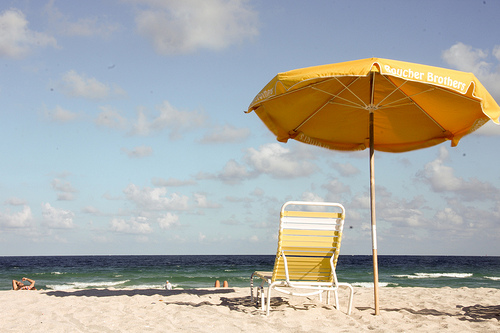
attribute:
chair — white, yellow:
[251, 213, 310, 281]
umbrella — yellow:
[370, 27, 428, 126]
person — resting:
[14, 261, 39, 293]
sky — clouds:
[169, 145, 275, 248]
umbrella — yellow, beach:
[250, 49, 498, 309]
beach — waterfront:
[19, 291, 469, 330]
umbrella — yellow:
[241, 54, 492, 329]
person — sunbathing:
[6, 270, 52, 296]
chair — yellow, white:
[256, 199, 359, 330]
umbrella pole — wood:
[362, 104, 385, 310]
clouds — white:
[38, 171, 222, 250]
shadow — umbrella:
[47, 286, 237, 297]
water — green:
[65, 257, 220, 276]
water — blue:
[121, 253, 216, 266]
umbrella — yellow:
[245, 55, 497, 180]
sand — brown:
[127, 310, 170, 326]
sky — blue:
[24, 95, 244, 190]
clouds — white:
[92, 171, 222, 241]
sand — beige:
[19, 278, 279, 328]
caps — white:
[390, 263, 482, 296]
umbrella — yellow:
[236, 45, 494, 184]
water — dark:
[6, 255, 498, 265]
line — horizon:
[1, 239, 498, 263]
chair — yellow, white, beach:
[236, 184, 371, 324]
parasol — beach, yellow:
[241, 41, 498, 184]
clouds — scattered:
[24, 185, 225, 240]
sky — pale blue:
[3, 9, 492, 255]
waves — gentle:
[395, 265, 477, 285]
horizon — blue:
[7, 239, 490, 260]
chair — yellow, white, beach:
[250, 199, 361, 319]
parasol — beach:
[236, 49, 490, 186]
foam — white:
[390, 265, 479, 286]